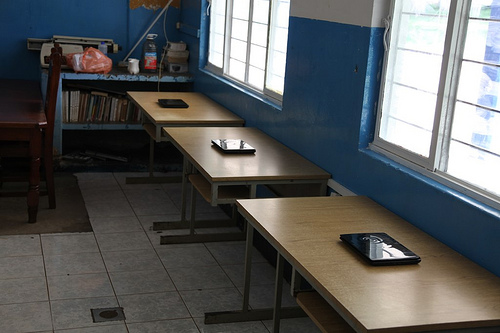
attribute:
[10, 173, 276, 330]
floor — tiled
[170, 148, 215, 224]
tray — under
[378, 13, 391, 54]
latch — window latch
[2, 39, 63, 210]
chair — brown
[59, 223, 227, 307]
tile — tan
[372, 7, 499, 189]
window — big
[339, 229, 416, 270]
laptop — small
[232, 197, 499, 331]
desk — wood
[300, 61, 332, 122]
wall — blue, white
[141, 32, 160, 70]
bottle — juice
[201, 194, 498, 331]
table — metal, gray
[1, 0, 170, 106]
wall — blue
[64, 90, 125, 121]
books — line